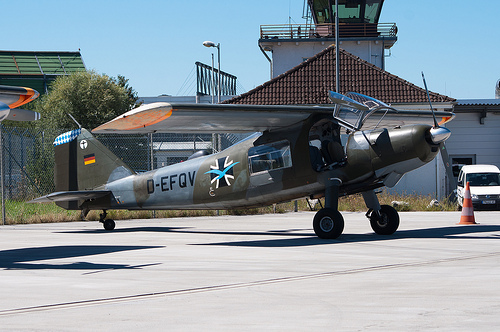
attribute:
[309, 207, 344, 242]
tire — black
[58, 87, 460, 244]
plane — brown, small, sitting, old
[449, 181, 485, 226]
cone — orange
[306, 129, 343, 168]
door — open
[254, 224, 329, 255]
shadow — black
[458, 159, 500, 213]
car — white, parked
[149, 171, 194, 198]
letters — black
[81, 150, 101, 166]
sticker — black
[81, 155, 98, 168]
flag — black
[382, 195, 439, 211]
grass — brown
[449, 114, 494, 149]
side — white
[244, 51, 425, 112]
roof — brown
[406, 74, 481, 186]
propeller — silver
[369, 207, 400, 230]
tire — black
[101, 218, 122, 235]
tire — black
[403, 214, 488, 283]
concrete — white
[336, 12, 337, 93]
post — white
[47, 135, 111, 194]
tail — grey